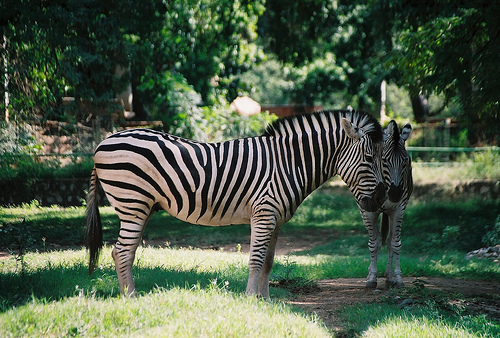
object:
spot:
[0, 283, 330, 336]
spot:
[358, 312, 479, 338]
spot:
[0, 244, 332, 274]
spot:
[0, 202, 119, 224]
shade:
[1, 214, 499, 255]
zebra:
[83, 109, 386, 301]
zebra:
[352, 116, 420, 297]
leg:
[297, 182, 338, 281]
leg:
[245, 202, 283, 305]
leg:
[365, 203, 381, 287]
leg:
[386, 203, 397, 286]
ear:
[340, 117, 366, 139]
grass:
[2, 152, 496, 338]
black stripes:
[85, 109, 413, 285]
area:
[0, 133, 499, 336]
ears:
[385, 119, 411, 142]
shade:
[270, 256, 497, 333]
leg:
[361, 215, 378, 289]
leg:
[390, 209, 404, 288]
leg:
[255, 215, 289, 302]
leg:
[114, 209, 152, 301]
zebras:
[83, 109, 412, 303]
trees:
[1, 2, 497, 137]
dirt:
[275, 226, 330, 255]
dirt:
[139, 235, 250, 254]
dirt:
[280, 273, 500, 336]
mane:
[261, 108, 382, 142]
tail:
[80, 163, 104, 278]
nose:
[372, 182, 385, 209]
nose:
[388, 183, 403, 203]